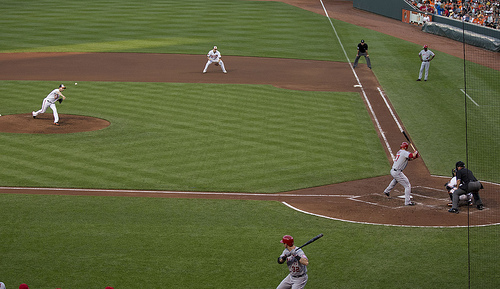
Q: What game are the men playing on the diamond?
A: Baseball.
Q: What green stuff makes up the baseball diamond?
A: Grass.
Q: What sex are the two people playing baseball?
A: Male.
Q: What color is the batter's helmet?
A: Red.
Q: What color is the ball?
A: White.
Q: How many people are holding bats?
A: Two.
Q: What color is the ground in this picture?
A: Green.